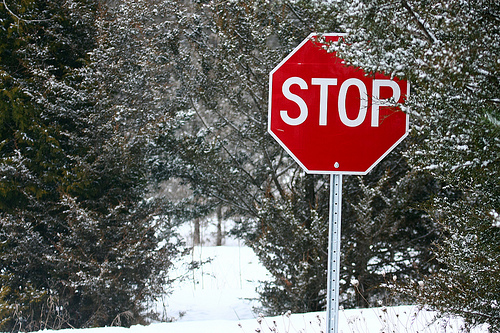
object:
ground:
[0, 201, 498, 331]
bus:
[263, 19, 418, 181]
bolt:
[328, 159, 343, 171]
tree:
[267, 1, 497, 331]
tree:
[103, 0, 295, 243]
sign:
[267, 28, 415, 178]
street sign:
[269, 32, 411, 173]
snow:
[2, 2, 498, 330]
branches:
[251, 136, 289, 197]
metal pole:
[317, 172, 350, 333]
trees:
[0, 0, 169, 324]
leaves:
[479, 310, 498, 329]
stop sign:
[263, 21, 423, 175]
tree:
[119, 24, 380, 322]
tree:
[3, 0, 220, 332]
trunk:
[214, 199, 224, 249]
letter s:
[278, 77, 309, 127]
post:
[321, 172, 342, 332]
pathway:
[158, 219, 274, 333]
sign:
[268, 30, 409, 331]